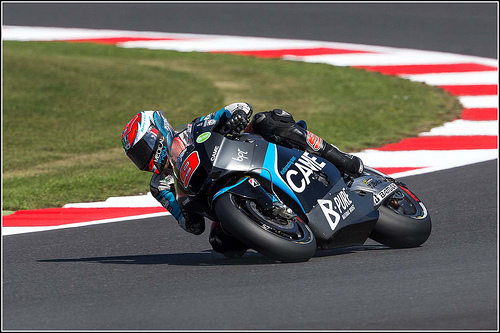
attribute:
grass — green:
[288, 95, 356, 131]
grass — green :
[3, 42, 453, 167]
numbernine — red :
[173, 144, 211, 194]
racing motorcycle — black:
[108, 98, 450, 270]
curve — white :
[9, 10, 499, 225]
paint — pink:
[11, 204, 121, 232]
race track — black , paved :
[5, 7, 498, 325]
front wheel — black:
[209, 186, 318, 263]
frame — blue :
[176, 132, 395, 231]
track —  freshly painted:
[107, 276, 178, 295]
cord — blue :
[238, 165, 286, 207]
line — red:
[392, 55, 483, 95]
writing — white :
[314, 200, 366, 220]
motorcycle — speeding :
[186, 136, 426, 243]